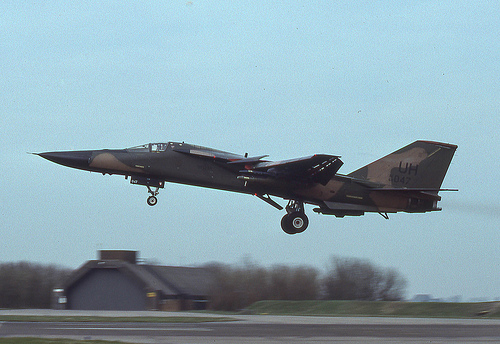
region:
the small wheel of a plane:
[147, 196, 161, 208]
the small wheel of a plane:
[279, 211, 292, 233]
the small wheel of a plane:
[288, 212, 307, 232]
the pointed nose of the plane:
[25, 145, 140, 175]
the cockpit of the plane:
[130, 140, 170, 156]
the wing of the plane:
[260, 153, 340, 186]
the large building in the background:
[52, 246, 232, 311]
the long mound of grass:
[243, 297, 498, 316]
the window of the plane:
[128, 141, 167, 153]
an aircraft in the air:
[12, 120, 467, 240]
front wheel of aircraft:
[141, 187, 162, 207]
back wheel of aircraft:
[277, 204, 312, 241]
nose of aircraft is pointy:
[21, 133, 104, 177]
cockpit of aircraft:
[119, 129, 195, 164]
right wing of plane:
[257, 145, 347, 190]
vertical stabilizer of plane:
[342, 132, 462, 188]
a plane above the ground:
[7, 109, 493, 342]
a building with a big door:
[38, 233, 222, 320]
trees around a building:
[0, 241, 405, 321]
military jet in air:
[44, 84, 479, 259]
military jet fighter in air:
[58, 140, 489, 232]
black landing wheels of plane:
[278, 210, 311, 231]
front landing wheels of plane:
[139, 182, 159, 212]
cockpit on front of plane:
[137, 133, 164, 153]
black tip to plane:
[25, 146, 104, 166]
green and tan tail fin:
[343, 135, 471, 197]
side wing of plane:
[259, 140, 348, 204]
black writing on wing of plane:
[378, 157, 421, 189]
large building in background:
[28, 240, 205, 329]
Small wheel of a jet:
[143, 193, 163, 211]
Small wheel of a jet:
[290, 213, 317, 228]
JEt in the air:
[19, 108, 494, 258]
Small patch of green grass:
[235, 296, 291, 313]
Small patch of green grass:
[287, 291, 320, 331]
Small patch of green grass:
[317, 287, 352, 317]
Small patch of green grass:
[348, 289, 388, 312]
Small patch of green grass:
[388, 298, 436, 321]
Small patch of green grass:
[432, 298, 482, 325]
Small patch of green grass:
[7, 308, 242, 330]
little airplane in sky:
[29, 132, 456, 228]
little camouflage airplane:
[31, 132, 456, 232]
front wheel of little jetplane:
[138, 173, 168, 209]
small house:
[59, 235, 187, 308]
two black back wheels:
[278, 194, 310, 241]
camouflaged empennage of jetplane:
[358, 128, 463, 190]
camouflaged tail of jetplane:
[353, 139, 466, 184]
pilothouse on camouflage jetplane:
[126, 134, 186, 155]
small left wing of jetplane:
[246, 149, 349, 181]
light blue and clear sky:
[0, 0, 499, 300]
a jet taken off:
[21, 120, 469, 242]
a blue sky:
[1, 1, 499, 271]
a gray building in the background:
[48, 238, 230, 329]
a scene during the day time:
[14, 15, 498, 305]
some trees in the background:
[1, 251, 403, 316]